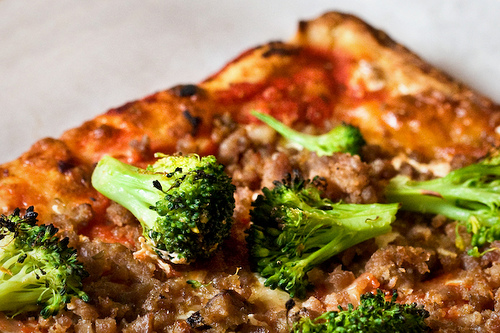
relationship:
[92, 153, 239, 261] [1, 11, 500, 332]
broccoli on pizza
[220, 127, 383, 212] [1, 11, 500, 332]
meat on pizza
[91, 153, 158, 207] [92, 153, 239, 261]
stems on broccoli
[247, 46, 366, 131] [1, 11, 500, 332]
sauce on pizza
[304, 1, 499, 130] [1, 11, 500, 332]
crust on pizza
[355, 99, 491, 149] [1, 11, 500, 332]
cheese on pizza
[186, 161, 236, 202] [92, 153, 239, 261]
florets on broccoli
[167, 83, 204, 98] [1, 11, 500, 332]
spots on pizza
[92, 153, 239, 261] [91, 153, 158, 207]
broccoli has stems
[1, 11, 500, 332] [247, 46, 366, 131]
pizza has sauce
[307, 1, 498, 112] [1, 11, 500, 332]
edge of pizza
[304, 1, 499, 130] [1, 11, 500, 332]
crust of pizza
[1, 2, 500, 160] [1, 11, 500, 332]
plate holds pizza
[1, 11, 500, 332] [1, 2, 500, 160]
pizza on table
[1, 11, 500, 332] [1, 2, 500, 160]
pizza on plate